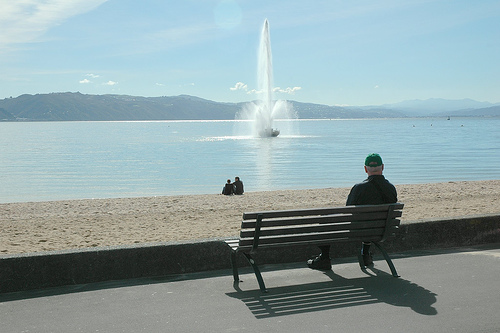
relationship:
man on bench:
[305, 152, 397, 273] [248, 170, 447, 270]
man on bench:
[305, 152, 397, 273] [200, 189, 445, 305]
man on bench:
[305, 152, 397, 273] [213, 185, 477, 294]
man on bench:
[305, 152, 397, 273] [205, 193, 423, 278]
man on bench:
[325, 144, 434, 270] [210, 200, 437, 290]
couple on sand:
[220, 176, 245, 196] [13, 193, 320, 267]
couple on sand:
[220, 176, 245, 196] [36, 207, 297, 254]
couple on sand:
[220, 176, 245, 196] [24, 182, 353, 255]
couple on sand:
[210, 166, 262, 201] [28, 200, 281, 267]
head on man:
[350, 156, 403, 179] [305, 152, 397, 273]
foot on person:
[301, 240, 373, 285] [290, 150, 450, 306]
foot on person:
[349, 232, 393, 264] [322, 152, 422, 278]